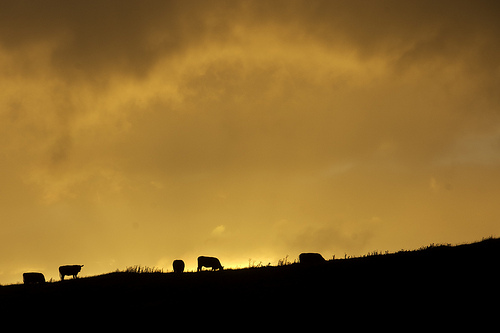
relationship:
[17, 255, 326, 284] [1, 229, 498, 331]
animals are on hill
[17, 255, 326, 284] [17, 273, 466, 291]
animals are in shadow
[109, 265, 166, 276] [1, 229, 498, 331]
grass grow on hill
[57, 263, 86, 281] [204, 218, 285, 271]
animals face sun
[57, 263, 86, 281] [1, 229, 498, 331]
animals walks over hill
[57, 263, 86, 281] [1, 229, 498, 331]
animals stands on hill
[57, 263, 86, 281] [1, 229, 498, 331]
animals on hill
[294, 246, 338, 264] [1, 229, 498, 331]
last cow on hill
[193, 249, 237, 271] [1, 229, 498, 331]
second cow on hill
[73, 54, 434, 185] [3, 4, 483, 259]
clouds are in sky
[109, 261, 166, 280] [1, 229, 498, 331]
grass on hill